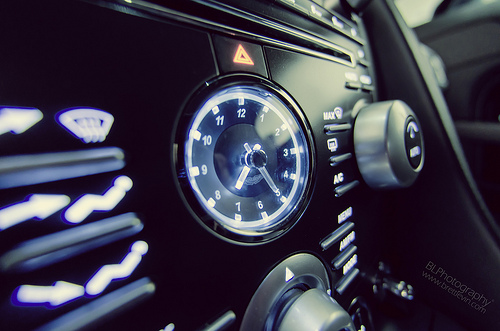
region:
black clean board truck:
[0, 5, 473, 320]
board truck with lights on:
[0, 5, 475, 325]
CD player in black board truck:
[135, 0, 370, 65]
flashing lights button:
[221, 35, 266, 66]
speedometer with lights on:
[176, 82, 317, 247]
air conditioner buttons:
[0, 162, 160, 317]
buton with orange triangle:
[216, 27, 263, 67]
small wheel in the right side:
[360, 90, 435, 196]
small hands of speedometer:
[225, 140, 280, 210]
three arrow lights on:
[0, 77, 85, 327]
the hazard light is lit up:
[212, 36, 266, 73]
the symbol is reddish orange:
[217, 37, 263, 70]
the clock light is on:
[172, 86, 319, 229]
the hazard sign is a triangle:
[220, 36, 263, 68]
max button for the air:
[308, 95, 354, 135]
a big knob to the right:
[337, 85, 439, 209]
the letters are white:
[315, 98, 343, 128]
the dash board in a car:
[44, 0, 473, 305]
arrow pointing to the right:
[7, 185, 90, 237]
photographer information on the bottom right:
[399, 252, 498, 329]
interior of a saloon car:
[181, 184, 248, 270]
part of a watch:
[220, 242, 240, 272]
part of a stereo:
[111, 26, 152, 257]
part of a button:
[222, 237, 242, 272]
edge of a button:
[333, 120, 340, 153]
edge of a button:
[375, 147, 381, 162]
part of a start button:
[110, 95, 136, 118]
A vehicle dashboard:
[4, 5, 494, 320]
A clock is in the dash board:
[166, 68, 322, 250]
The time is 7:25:
[230, 135, 292, 232]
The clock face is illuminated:
[184, 82, 311, 235]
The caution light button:
[206, 30, 269, 75]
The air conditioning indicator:
[331, 172, 363, 199]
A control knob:
[351, 92, 431, 203]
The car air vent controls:
[1, 98, 162, 328]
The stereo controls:
[192, 210, 412, 330]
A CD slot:
[104, 0, 370, 66]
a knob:
[352, 112, 429, 178]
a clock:
[189, 106, 315, 221]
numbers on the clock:
[199, 162, 253, 214]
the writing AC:
[327, 172, 359, 188]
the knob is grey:
[282, 302, 364, 328]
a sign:
[6, 245, 176, 317]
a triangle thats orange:
[225, 31, 265, 71]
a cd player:
[275, 16, 317, 48]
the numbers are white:
[186, 127, 216, 188]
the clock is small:
[178, 95, 336, 223]